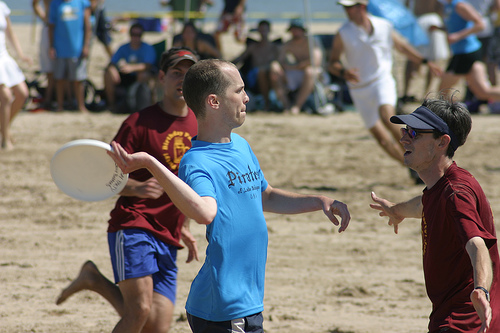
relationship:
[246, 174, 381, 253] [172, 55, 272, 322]
hand on man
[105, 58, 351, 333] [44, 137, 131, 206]
man holding frisbee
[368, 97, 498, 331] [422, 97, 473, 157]
man has dark hair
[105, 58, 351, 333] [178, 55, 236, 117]
man has hair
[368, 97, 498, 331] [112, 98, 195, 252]
man wearing a shirt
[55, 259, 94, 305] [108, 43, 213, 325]
foot of a person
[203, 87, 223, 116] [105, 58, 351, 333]
ear of a man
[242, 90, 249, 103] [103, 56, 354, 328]
nose of a person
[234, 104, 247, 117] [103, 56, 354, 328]
mouth of a person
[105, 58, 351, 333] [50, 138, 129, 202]
man playing frisbee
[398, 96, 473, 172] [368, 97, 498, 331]
head of an man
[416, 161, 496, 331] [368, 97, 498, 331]
red shirt of a man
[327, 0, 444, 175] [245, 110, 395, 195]
person running on beach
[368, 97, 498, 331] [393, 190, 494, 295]
man with arms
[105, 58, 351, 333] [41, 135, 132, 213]
man playing with frisbee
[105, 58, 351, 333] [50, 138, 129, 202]
man throwing a frisbee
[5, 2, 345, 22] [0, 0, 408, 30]
water in background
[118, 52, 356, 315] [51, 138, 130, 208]
man has a frisbee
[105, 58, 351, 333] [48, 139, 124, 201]
man holding frisbee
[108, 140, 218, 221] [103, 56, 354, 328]
arm on person